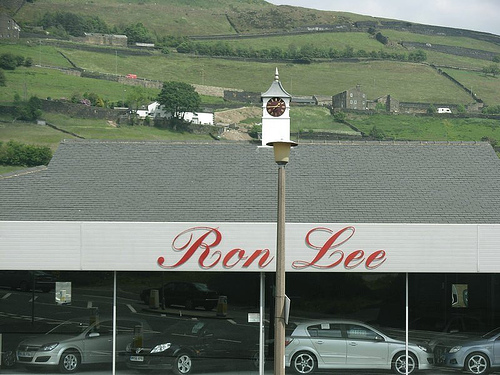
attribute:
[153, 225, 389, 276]
letters — red, large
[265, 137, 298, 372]
pole — beige, white, tan, metal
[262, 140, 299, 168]
light — tan, white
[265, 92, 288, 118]
clock — wall, brown, black, gold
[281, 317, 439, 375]
car — parked, white, silver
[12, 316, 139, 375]
car — parked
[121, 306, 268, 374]
car — black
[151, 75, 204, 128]
tree — large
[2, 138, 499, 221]
roof — black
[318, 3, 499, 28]
sky — cloudy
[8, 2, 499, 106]
hill — huge, green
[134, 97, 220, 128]
house — white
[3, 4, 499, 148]
grass — green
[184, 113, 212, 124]
wall — whiye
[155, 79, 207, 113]
leaves — green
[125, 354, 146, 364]
license plate — white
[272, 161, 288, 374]
post — metal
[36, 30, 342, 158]
leaves — green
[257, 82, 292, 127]
numbers — gold